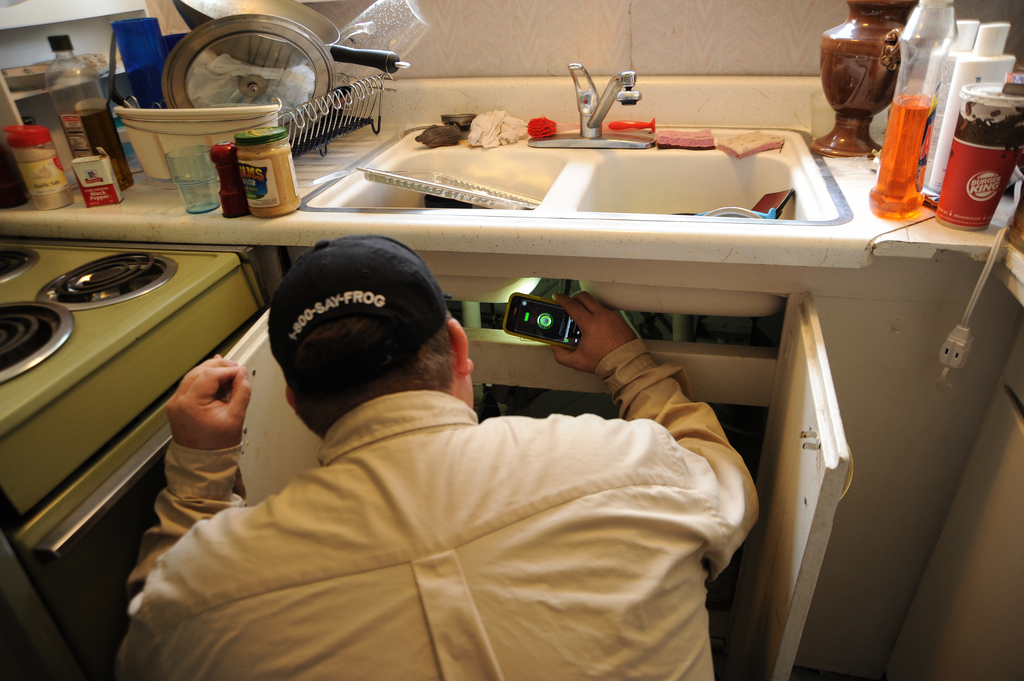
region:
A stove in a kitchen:
[6, 229, 266, 676]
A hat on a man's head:
[268, 234, 450, 378]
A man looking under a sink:
[109, 232, 758, 676]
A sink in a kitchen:
[305, 114, 840, 229]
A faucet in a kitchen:
[518, 57, 649, 153]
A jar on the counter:
[236, 126, 306, 221]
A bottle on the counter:
[39, 29, 141, 204]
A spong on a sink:
[720, 130, 782, 159]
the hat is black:
[270, 230, 451, 389]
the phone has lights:
[503, 291, 581, 350]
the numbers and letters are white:
[291, 285, 384, 334]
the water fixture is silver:
[526, 59, 657, 152]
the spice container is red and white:
[70, 143, 124, 208]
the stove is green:
[5, 230, 255, 676]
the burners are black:
[0, 240, 175, 399]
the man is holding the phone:
[118, 228, 768, 675]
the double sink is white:
[296, 119, 843, 228]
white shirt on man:
[114, 345, 781, 678]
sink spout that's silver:
[555, 50, 651, 155]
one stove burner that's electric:
[40, 247, 186, 323]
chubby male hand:
[169, 345, 256, 459]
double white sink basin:
[318, 104, 832, 247]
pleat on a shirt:
[381, 519, 528, 674]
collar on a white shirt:
[301, 383, 491, 478]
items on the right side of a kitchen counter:
[813, 4, 1019, 248]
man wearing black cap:
[105, 231, 763, 677]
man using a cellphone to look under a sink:
[112, 233, 760, 677]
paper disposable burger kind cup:
[925, 73, 1021, 235]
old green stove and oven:
[0, 236, 266, 679]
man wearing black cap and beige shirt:
[106, 230, 762, 677]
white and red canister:
[64, 142, 126, 210]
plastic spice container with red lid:
[1, 119, 79, 212]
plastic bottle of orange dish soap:
[866, 2, 956, 215]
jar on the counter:
[234, 123, 302, 229]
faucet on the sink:
[561, 45, 651, 150]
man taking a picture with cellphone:
[95, 224, 767, 678]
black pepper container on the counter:
[73, 143, 116, 213]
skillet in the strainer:
[136, 6, 343, 114]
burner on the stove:
[33, 249, 170, 314]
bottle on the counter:
[39, 22, 109, 146]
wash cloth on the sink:
[466, 105, 528, 153]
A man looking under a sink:
[162, 247, 745, 677]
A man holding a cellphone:
[113, 203, 728, 674]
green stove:
[7, 238, 265, 676]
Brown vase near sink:
[807, 0, 899, 154]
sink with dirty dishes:
[301, 63, 852, 228]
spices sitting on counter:
[10, 121, 124, 220]